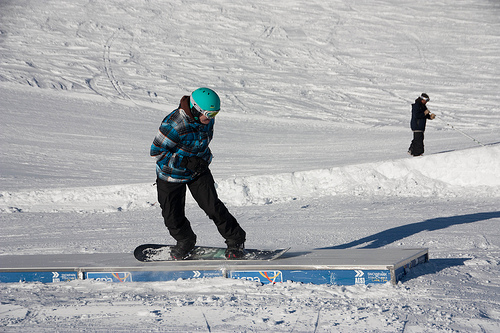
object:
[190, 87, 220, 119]
helmet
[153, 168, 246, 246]
pants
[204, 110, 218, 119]
goggles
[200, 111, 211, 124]
face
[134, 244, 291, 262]
snowboard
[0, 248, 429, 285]
ramp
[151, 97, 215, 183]
jacket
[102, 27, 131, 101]
track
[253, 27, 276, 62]
track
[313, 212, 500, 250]
shadow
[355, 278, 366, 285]
letters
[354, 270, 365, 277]
arrows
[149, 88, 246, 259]
person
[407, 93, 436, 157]
person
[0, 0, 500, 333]
ground